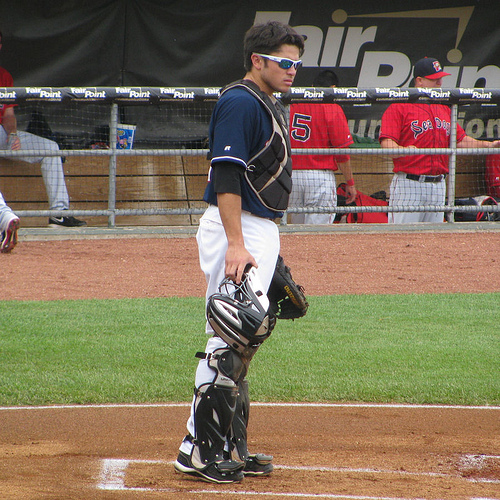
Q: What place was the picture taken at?
A: It was taken at the field.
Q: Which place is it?
A: It is a field.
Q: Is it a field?
A: Yes, it is a field.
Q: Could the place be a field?
A: Yes, it is a field.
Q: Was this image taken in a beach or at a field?
A: It was taken at a field.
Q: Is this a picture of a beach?
A: No, the picture is showing a field.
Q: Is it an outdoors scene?
A: Yes, it is outdoors.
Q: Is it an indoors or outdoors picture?
A: It is outdoors.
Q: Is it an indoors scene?
A: No, it is outdoors.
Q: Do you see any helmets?
A: Yes, there is a helmet.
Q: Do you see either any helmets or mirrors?
A: Yes, there is a helmet.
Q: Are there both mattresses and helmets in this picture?
A: No, there is a helmet but no mattresses.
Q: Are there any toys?
A: No, there are no toys.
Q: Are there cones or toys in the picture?
A: No, there are no toys or cones.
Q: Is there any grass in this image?
A: Yes, there is grass.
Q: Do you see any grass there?
A: Yes, there is grass.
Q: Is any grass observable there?
A: Yes, there is grass.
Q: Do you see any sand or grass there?
A: Yes, there is grass.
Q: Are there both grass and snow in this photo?
A: No, there is grass but no snow.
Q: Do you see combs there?
A: No, there are no combs.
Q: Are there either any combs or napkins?
A: No, there are no combs or napkins.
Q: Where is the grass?
A: The grass is on the field.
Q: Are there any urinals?
A: No, there are no urinals.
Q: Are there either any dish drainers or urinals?
A: No, there are no urinals or dish drainers.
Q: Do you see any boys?
A: No, there are no boys.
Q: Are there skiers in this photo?
A: No, there are no skiers.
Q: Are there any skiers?
A: No, there are no skiers.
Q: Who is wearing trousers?
A: The player is wearing trousers.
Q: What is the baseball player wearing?
A: The player is wearing pants.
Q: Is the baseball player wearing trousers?
A: Yes, the player is wearing trousers.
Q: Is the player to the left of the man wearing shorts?
A: No, the player is wearing trousers.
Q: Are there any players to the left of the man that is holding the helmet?
A: Yes, there is a player to the left of the man.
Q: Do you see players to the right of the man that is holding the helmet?
A: No, the player is to the left of the man.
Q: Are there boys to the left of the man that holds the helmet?
A: No, there is a player to the left of the man.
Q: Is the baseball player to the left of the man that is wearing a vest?
A: Yes, the player is to the left of the man.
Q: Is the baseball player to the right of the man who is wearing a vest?
A: No, the player is to the left of the man.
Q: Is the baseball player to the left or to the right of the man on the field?
A: The player is to the left of the man.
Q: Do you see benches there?
A: Yes, there is a bench.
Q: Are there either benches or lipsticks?
A: Yes, there is a bench.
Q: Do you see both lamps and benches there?
A: No, there is a bench but no lamps.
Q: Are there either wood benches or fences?
A: Yes, there is a wood bench.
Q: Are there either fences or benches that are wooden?
A: Yes, the bench is wooden.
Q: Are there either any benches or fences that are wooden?
A: Yes, the bench is wooden.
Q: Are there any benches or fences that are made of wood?
A: Yes, the bench is made of wood.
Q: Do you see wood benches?
A: Yes, there is a wood bench.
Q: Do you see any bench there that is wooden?
A: Yes, there is a bench that is wooden.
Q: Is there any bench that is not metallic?
A: Yes, there is a wooden bench.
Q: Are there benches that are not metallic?
A: Yes, there is a wooden bench.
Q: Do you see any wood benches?
A: Yes, there is a bench that is made of wood.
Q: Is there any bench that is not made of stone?
A: Yes, there is a bench that is made of wood.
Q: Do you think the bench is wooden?
A: Yes, the bench is wooden.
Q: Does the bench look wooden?
A: Yes, the bench is wooden.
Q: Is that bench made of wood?
A: Yes, the bench is made of wood.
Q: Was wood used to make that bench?
A: Yes, the bench is made of wood.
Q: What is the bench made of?
A: The bench is made of wood.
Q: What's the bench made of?
A: The bench is made of wood.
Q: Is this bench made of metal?
A: No, the bench is made of wood.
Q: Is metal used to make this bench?
A: No, the bench is made of wood.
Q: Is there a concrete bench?
A: No, there is a bench but it is made of wood.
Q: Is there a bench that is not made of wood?
A: No, there is a bench but it is made of wood.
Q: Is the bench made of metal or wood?
A: The bench is made of wood.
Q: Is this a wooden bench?
A: Yes, this is a wooden bench.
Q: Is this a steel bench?
A: No, this is a wooden bench.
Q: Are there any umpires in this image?
A: No, there are no umpires.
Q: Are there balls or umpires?
A: No, there are no umpires or balls.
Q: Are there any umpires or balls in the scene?
A: No, there are no umpires or balls.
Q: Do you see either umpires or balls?
A: No, there are no umpires or balls.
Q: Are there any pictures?
A: No, there are no pictures.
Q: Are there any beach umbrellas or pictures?
A: No, there are no pictures or beach umbrellas.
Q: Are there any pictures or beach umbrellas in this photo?
A: No, there are no pictures or beach umbrellas.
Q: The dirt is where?
A: The dirt is on the field.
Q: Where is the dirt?
A: The dirt is on the field.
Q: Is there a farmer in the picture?
A: No, there are no farmers.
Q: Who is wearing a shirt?
A: The man is wearing a shirt.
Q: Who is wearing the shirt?
A: The man is wearing a shirt.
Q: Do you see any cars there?
A: No, there are no cars.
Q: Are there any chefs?
A: No, there are no chefs.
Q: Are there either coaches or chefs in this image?
A: No, there are no chefs or coaches.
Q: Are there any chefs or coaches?
A: No, there are no chefs or coaches.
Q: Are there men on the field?
A: Yes, there is a man on the field.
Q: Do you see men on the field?
A: Yes, there is a man on the field.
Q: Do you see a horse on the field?
A: No, there is a man on the field.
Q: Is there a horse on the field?
A: No, there is a man on the field.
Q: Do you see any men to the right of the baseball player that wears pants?
A: Yes, there is a man to the right of the player.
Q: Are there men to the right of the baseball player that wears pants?
A: Yes, there is a man to the right of the player.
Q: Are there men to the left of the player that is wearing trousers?
A: No, the man is to the right of the player.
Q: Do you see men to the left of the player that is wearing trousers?
A: No, the man is to the right of the player.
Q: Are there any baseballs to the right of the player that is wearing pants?
A: No, there is a man to the right of the player.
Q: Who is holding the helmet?
A: The man is holding the helmet.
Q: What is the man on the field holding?
A: The man is holding the helmet.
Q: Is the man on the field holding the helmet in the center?
A: Yes, the man is holding the helmet.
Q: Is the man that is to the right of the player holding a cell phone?
A: No, the man is holding the helmet.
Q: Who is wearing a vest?
A: The man is wearing a vest.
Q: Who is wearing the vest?
A: The man is wearing a vest.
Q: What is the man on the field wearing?
A: The man is wearing a vest.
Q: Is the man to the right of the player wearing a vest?
A: Yes, the man is wearing a vest.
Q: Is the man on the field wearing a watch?
A: No, the man is wearing a vest.